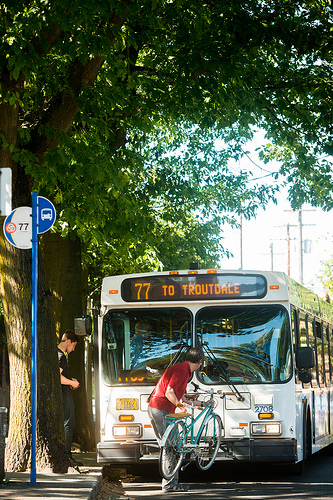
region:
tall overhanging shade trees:
[1, 1, 332, 476]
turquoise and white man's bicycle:
[156, 379, 225, 481]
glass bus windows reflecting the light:
[98, 298, 294, 389]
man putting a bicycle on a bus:
[146, 345, 227, 492]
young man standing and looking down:
[53, 328, 84, 466]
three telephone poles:
[256, 201, 318, 283]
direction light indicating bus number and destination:
[119, 272, 268, 303]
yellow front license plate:
[114, 396, 139, 410]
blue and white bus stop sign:
[0, 188, 57, 486]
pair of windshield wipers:
[145, 340, 245, 403]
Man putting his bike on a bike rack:
[146, 345, 223, 492]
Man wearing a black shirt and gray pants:
[58, 327, 83, 467]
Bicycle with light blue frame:
[157, 382, 236, 480]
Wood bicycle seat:
[165, 410, 193, 419]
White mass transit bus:
[97, 268, 332, 476]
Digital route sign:
[126, 272, 256, 302]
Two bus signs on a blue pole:
[3, 188, 55, 485]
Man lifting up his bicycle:
[146, 345, 224, 493]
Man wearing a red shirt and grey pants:
[147, 346, 204, 492]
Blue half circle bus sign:
[36, 196, 56, 233]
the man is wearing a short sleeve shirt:
[149, 361, 192, 414]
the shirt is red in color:
[152, 361, 190, 407]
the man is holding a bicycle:
[156, 366, 224, 478]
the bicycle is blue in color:
[170, 393, 214, 457]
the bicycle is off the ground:
[152, 389, 233, 472]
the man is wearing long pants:
[144, 405, 180, 487]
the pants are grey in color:
[146, 405, 181, 486]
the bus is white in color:
[100, 275, 328, 456]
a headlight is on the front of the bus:
[109, 422, 144, 438]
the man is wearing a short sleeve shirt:
[51, 347, 73, 392]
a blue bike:
[158, 383, 225, 479]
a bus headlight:
[251, 425, 279, 434]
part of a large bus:
[91, 263, 331, 471]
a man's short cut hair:
[182, 345, 204, 363]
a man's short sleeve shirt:
[146, 362, 191, 413]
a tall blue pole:
[4, 191, 59, 485]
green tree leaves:
[317, 272, 332, 294]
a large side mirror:
[72, 317, 90, 336]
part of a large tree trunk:
[0, 270, 68, 474]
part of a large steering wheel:
[238, 348, 269, 367]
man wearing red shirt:
[150, 347, 205, 493]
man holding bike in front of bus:
[149, 342, 232, 495]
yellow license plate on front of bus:
[114, 396, 140, 409]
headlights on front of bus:
[251, 422, 281, 434]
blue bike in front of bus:
[160, 386, 227, 484]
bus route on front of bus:
[121, 275, 267, 301]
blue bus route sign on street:
[2, 189, 56, 487]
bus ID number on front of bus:
[253, 402, 275, 412]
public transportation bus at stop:
[98, 272, 332, 480]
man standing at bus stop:
[55, 326, 83, 470]